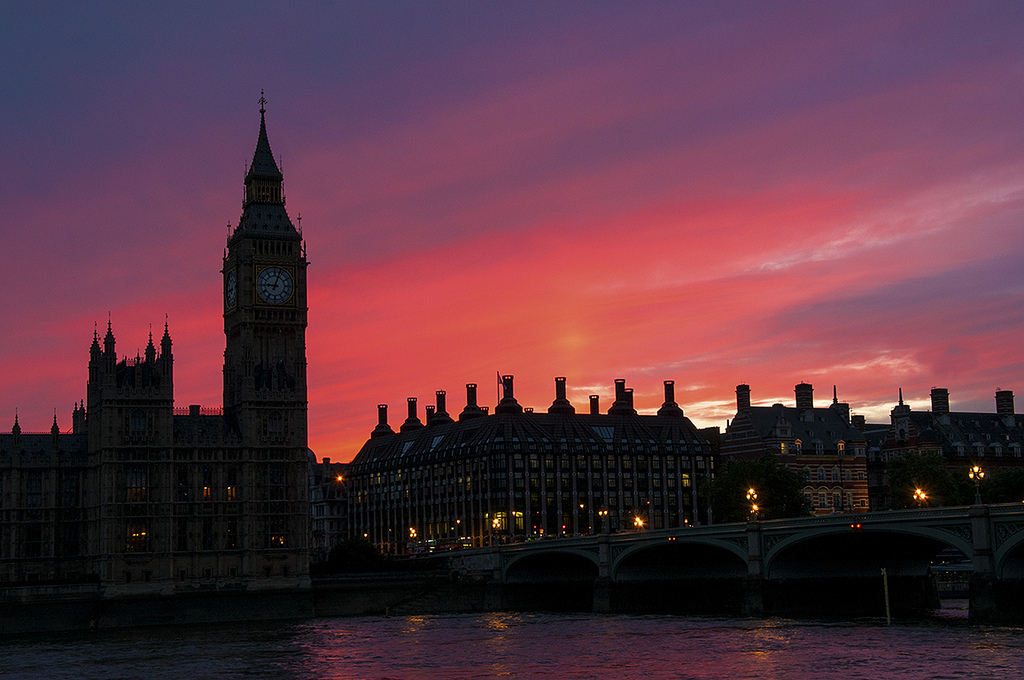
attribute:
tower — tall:
[155, 78, 408, 515]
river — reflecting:
[300, 608, 877, 671]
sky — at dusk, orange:
[11, 18, 1014, 397]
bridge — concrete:
[413, 492, 1011, 620]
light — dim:
[126, 514, 161, 552]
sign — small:
[934, 589, 983, 629]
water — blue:
[275, 610, 1023, 671]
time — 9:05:
[256, 262, 302, 308]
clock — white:
[243, 256, 306, 317]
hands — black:
[269, 279, 295, 299]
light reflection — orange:
[403, 608, 434, 637]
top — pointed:
[252, 83, 278, 142]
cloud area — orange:
[329, 249, 785, 401]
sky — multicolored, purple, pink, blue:
[5, 3, 1021, 470]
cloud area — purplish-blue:
[3, 3, 222, 151]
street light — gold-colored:
[740, 498, 769, 524]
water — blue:
[280, 605, 998, 677]